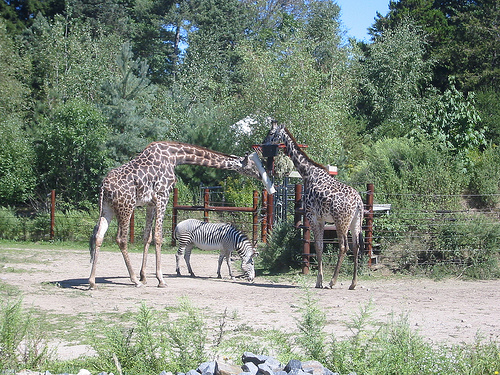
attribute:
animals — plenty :
[92, 111, 382, 286]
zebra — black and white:
[176, 209, 263, 274]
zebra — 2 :
[169, 216, 266, 277]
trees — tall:
[10, 10, 478, 214]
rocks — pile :
[154, 336, 314, 373]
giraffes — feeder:
[75, 93, 371, 286]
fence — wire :
[51, 180, 468, 263]